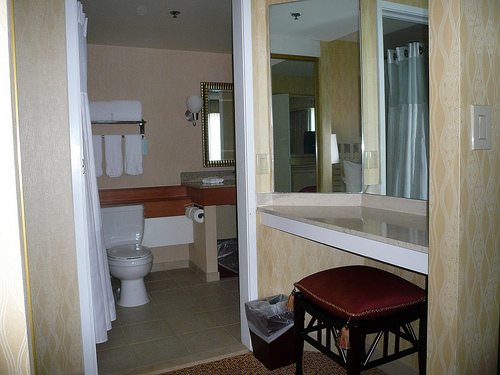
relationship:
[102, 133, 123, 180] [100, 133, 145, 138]
towel hanging on rod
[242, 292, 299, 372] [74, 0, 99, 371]
trash can standing near door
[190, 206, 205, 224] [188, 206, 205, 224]
toilet paper wrapped around toilet paper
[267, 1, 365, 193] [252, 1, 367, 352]
mirror hanging on wall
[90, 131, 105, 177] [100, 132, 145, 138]
towel hanging on rod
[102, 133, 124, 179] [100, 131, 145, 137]
towel hanging on rod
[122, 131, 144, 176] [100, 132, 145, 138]
towel hanging on rod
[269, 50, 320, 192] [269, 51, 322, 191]
reflection showing mirror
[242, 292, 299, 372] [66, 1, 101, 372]
trash can standing near door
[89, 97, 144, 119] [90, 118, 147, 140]
towels on rack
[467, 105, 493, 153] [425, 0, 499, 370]
light switch on wall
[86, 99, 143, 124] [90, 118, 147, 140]
towels on rack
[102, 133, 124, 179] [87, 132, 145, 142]
towel hanging on towel rack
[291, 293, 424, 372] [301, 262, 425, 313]
stool with pillow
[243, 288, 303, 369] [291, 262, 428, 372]
trash can near black stool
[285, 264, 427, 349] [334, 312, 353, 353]
pillow with tassel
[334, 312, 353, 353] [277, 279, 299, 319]
tassel with tassel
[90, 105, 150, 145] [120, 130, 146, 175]
rack full of towel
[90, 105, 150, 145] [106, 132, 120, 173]
rack full of towel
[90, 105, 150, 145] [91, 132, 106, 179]
rack full of towel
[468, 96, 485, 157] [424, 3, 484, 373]
light switch on wall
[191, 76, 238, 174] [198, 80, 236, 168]
mirror with mirror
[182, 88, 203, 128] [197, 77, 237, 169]
light near mirror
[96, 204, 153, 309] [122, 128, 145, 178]
toilet under towel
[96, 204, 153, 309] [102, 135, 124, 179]
toilet under towel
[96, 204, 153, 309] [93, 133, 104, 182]
toilet under towel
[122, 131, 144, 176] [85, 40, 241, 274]
towel hanging on wall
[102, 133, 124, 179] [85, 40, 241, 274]
towel hanging on wall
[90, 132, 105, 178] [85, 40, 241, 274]
towel hanging on wall